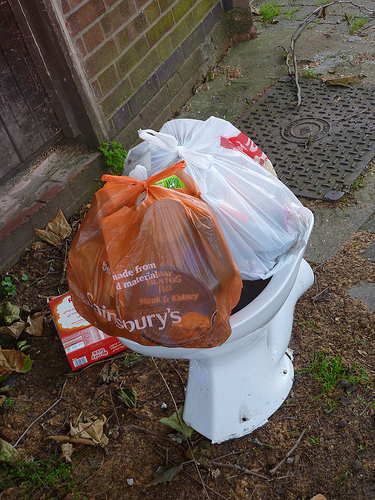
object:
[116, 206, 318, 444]
porcelain toilet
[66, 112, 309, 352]
garbage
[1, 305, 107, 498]
leaves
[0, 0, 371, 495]
ground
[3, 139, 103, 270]
steps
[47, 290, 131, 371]
box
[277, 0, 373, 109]
twig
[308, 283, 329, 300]
twig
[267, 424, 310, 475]
twig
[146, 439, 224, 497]
twig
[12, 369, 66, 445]
twig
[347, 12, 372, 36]
clump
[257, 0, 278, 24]
clump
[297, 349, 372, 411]
clump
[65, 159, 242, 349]
bag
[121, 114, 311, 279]
bag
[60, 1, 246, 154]
bricks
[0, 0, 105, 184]
bad door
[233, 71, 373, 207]
grate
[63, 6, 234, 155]
wall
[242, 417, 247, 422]
screw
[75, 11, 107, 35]
line